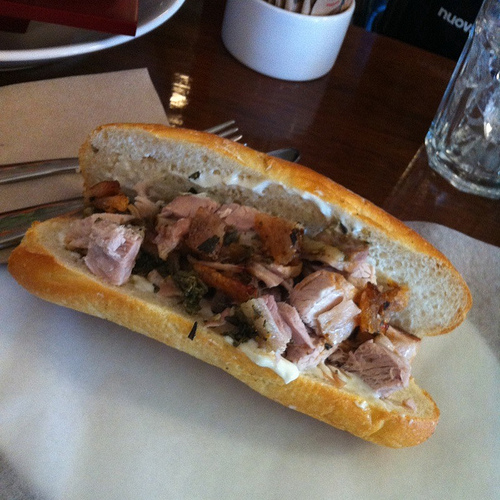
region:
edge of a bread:
[108, 307, 145, 337]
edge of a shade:
[181, 410, 231, 452]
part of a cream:
[351, 341, 396, 388]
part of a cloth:
[126, 437, 171, 487]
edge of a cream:
[292, 322, 314, 369]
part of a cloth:
[111, 421, 165, 472]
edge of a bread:
[411, 312, 453, 347]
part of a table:
[163, 453, 202, 487]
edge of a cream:
[281, 306, 319, 350]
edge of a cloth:
[1, 450, 40, 487]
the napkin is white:
[285, 460, 307, 485]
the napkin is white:
[242, 433, 259, 468]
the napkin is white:
[248, 456, 261, 475]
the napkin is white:
[249, 440, 273, 486]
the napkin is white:
[242, 478, 254, 493]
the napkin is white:
[247, 449, 269, 466]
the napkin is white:
[262, 448, 290, 490]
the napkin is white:
[236, 437, 257, 484]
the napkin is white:
[228, 468, 255, 498]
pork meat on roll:
[90, 162, 418, 389]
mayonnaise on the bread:
[161, 136, 396, 240]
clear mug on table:
[416, 15, 498, 222]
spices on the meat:
[144, 227, 309, 347]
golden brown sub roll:
[23, 106, 405, 353]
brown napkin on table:
[4, 76, 229, 176]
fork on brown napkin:
[28, 94, 324, 199]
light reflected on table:
[130, 41, 240, 135]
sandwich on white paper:
[265, 150, 467, 499]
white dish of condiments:
[205, 4, 400, 103]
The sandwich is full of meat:
[49, 122, 494, 395]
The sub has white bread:
[48, 136, 438, 421]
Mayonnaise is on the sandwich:
[205, 158, 385, 251]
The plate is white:
[56, 342, 248, 478]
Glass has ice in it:
[418, 13, 498, 220]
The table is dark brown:
[339, 134, 432, 213]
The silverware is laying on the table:
[2, 112, 287, 203]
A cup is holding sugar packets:
[224, 1, 381, 106]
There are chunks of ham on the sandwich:
[277, 273, 364, 364]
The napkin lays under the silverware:
[5, 84, 127, 209]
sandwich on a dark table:
[21, 20, 478, 470]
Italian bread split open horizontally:
[10, 85, 480, 455]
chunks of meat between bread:
[45, 155, 435, 405]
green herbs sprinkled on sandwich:
[130, 197, 320, 354]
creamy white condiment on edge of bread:
[155, 140, 375, 257]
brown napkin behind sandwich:
[10, 61, 285, 193]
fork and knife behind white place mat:
[0, 140, 315, 240]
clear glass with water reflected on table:
[385, 10, 491, 220]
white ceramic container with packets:
[210, 0, 360, 87]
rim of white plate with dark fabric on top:
[0, 1, 206, 67]